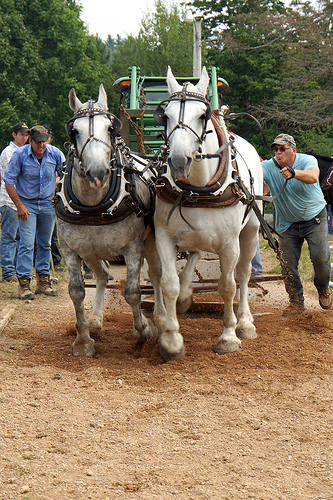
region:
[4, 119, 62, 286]
a guy wearing a blue shirt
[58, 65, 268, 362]
two horses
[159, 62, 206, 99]
the ears of a horse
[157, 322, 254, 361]
the horse's big feet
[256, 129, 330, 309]
a guy wearing a light blue shirt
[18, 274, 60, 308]
a pair of brown boots.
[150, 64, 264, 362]
a white horse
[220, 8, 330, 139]
the branches of a leafless tree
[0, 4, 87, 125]
a bushy tree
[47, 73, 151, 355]
a white and grey horse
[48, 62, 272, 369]
two white horses pulling a plow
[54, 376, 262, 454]
footprints in the dirt and sand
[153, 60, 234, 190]
white horse head with reins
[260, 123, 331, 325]
man steering a horse plow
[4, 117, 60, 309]
men watching the horse plow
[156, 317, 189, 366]
large hoof of a white horse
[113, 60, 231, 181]
green tractor behind horses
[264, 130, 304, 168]
man in a baseball cap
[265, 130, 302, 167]
man in sunglasses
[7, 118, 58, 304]
man in work clothes and boots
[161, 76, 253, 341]
horse on right pulling plow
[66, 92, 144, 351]
horse on left pulling plow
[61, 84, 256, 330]
large white work horses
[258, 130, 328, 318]
man steering horses and plow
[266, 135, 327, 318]
man wearing hat and sunglasses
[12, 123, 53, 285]
men watch from behind horses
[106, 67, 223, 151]
green machine behind horses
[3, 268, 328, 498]
brown dirt ground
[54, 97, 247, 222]
black and brown leather harnesses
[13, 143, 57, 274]
denim shirt and denim pants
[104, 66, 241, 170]
a green tractor pulled by horses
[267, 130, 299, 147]
a camouflage cap on a man's head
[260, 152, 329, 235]
a light blue shirt on a man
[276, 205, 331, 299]
gray pants on a man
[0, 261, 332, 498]
trampled brown dirt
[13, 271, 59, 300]
brown boots on a man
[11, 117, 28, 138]
a black cap with yellow writing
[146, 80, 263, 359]
a large white draft horse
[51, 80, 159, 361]
a grayish white draft horse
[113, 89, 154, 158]
a chain attached to a tractor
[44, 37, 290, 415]
Two white horses working hard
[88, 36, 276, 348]
Pulling a green tractor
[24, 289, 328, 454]
Tearing up the dirt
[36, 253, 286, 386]
Horse hooves stomping the ground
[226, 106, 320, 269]
Holding leather strap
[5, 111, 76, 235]
Man with visor looks on intently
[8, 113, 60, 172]
Wearing caps an visors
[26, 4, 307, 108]
Green trees in the background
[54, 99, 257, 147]
Blinders on the horses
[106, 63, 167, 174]
Chains attached to the machine